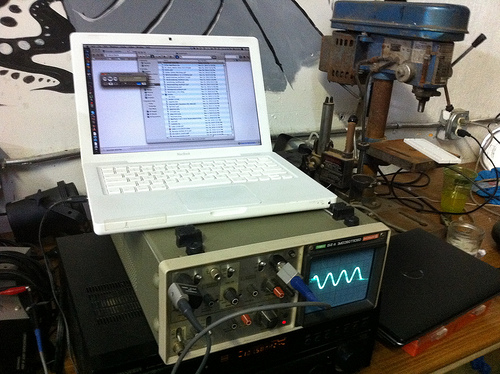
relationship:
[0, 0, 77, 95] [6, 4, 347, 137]
designs on wall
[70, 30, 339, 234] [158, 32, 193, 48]
laptop has webcam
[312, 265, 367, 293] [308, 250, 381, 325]
lines on oscilloscope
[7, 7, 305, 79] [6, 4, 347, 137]
designs painted on wall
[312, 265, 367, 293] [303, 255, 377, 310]
lines on screen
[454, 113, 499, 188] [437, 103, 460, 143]
cords plugged into box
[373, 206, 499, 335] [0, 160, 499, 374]
laptop on top of table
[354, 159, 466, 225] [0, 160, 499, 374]
wires on table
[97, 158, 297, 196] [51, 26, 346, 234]
keyboard attached to laptop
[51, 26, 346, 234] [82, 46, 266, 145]
laptop has computer screen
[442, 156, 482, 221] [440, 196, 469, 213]
glass has water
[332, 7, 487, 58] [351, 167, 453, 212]
machine has plugs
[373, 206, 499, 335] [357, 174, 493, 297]
laptop on table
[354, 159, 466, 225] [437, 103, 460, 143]
wires plugged to box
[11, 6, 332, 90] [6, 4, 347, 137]
painting on wall